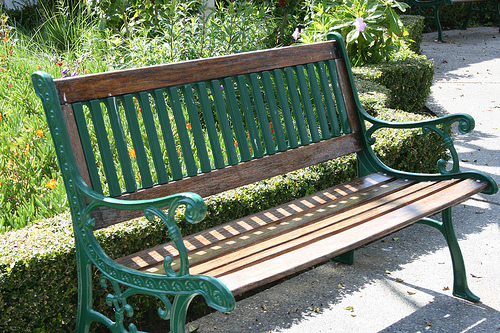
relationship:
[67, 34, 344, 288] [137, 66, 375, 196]
bench has back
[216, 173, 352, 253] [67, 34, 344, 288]
seat of bench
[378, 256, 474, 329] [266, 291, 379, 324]
shadow on ground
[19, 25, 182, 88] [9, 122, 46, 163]
bushes near flowers